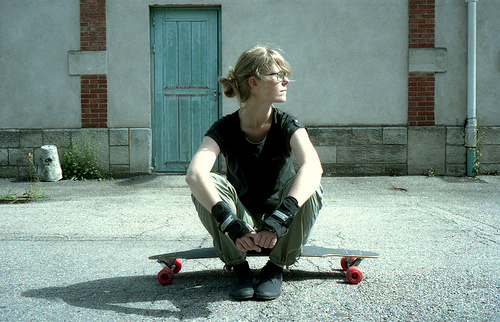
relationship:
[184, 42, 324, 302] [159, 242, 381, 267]
woman on a skateboard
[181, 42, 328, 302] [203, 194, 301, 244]
woman wearing wristbands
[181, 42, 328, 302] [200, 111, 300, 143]
woman has sleeves